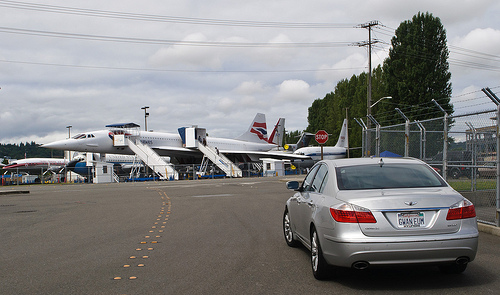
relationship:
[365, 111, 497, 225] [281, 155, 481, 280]
fence near car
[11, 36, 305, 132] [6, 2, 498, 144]
clouds in sky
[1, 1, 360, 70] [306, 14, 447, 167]
power lines near trees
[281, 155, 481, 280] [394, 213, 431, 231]
car has license plate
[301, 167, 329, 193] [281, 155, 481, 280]
windows on car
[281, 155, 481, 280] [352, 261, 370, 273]
car has exhaust pipe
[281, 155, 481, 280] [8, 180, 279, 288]
car on road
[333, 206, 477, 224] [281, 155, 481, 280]
lights on car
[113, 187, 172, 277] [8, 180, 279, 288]
dots on road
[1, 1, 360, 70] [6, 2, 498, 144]
power lines in sky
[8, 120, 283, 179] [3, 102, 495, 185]
airplanes at airport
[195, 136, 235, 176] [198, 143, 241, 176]
people on ramp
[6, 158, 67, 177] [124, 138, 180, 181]
plane has ramp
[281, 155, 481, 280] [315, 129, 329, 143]
car near stop sign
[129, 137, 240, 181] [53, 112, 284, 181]
ramps on plane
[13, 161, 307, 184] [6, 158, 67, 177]
fence in front of plane